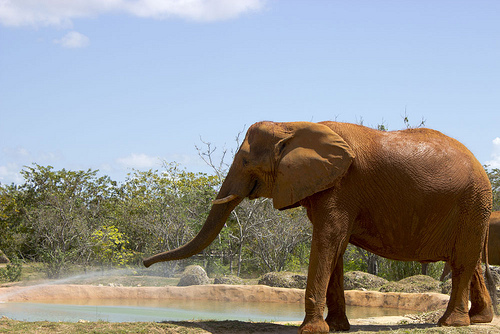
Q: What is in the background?
A: Trees.